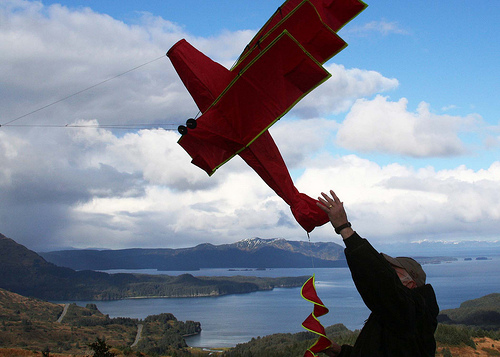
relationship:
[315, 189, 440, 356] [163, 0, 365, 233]
man releasing kite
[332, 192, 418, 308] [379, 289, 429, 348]
man wearing jacket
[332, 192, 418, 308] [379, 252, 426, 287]
man wearing baseball cap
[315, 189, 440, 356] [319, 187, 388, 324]
man with outreached arm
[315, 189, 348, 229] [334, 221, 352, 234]
hand with watch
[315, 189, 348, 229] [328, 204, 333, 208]
hand with ring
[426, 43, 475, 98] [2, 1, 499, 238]
sky in distance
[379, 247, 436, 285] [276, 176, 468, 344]
baseball cap on a man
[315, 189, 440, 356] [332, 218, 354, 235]
man wearing watch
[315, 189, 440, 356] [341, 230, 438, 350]
man wearing jacket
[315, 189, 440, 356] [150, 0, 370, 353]
man flying kite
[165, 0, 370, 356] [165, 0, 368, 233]
kite shaped like airplane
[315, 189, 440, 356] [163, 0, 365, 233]
man holding kite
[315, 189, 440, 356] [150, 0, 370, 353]
man has kite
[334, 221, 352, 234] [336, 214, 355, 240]
watch on wrist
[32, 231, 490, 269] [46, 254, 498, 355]
land behind water